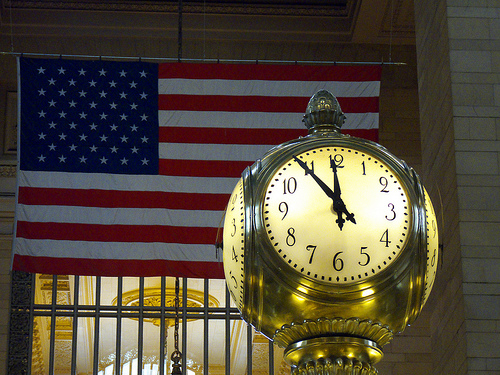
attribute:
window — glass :
[14, 275, 218, 374]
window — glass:
[202, 279, 229, 308]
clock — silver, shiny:
[261, 142, 413, 287]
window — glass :
[36, 270, 64, 308]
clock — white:
[218, 131, 431, 318]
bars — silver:
[24, 258, 303, 373]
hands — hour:
[291, 145, 352, 235]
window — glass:
[34, 277, 101, 374]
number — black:
[280, 177, 299, 197]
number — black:
[277, 201, 292, 222]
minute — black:
[295, 153, 335, 208]